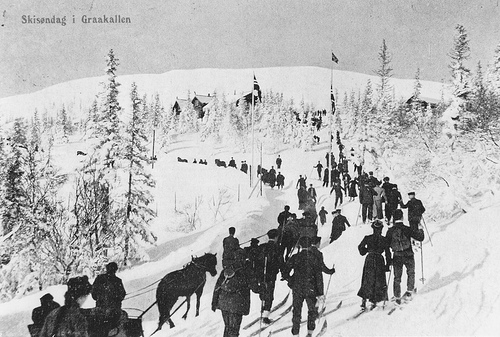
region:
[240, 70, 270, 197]
There is a flag on a pole.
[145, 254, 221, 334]
A black horse is walking.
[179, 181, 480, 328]
People are skiing up a hill.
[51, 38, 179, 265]
The trees are tall.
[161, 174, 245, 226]
The snow is white.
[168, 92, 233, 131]
There is a house on the hill.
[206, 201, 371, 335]
The people are wearing black.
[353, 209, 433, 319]
The are skiing next to each other.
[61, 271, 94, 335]
The lady is wearing a hat.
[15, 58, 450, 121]
The mountain is white.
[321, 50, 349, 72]
part of a flag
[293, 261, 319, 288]
part of a coat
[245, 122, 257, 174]
part of a post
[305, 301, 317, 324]
part of a trouser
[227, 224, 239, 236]
part of a marvin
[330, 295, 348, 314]
tip of a board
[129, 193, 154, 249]
part of a tree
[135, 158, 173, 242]
part of some tree branches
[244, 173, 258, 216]
edge of the footpath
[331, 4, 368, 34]
part of a hill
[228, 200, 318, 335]
these are people skating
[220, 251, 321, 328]
they are worn in black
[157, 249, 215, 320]
this is a horse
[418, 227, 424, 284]
the hand is holding a stick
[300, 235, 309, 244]
the man is wearing a cap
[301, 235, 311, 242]
the cap is black in color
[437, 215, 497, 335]
the place is full of snow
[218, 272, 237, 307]
this is a bag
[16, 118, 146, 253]
the tree is full of snow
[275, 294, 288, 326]
these are skiis on the mans legs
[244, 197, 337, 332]
person wearing black suit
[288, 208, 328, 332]
person wearing black suit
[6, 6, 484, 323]
Photo taken in the winter.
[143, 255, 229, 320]
Horse towing a sleigh.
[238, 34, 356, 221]
Flag posts along the trail.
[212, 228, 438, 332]
People with skis on.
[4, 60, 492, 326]
Snow on the ground.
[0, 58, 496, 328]
The ground is white.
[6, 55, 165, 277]
Trees lining the trail.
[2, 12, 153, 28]
Skisondag i Graakallen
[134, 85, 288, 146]
Building in the distance.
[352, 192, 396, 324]
Woman with a dress skiing.